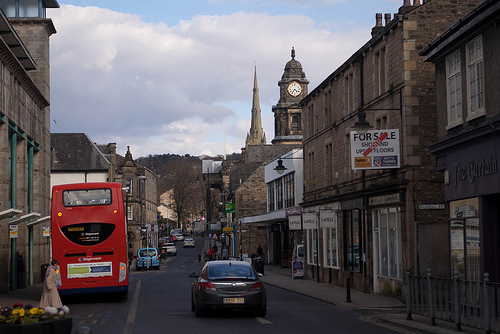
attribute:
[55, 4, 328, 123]
clouds — white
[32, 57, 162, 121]
clouds — white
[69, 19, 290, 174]
sky — blue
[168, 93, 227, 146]
clouds — white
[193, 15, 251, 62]
clouds — white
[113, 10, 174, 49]
clouds — white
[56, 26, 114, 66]
clouds — white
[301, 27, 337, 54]
clouds — white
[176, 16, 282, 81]
clouds — white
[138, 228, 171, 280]
van — blue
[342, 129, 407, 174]
sign — black, white, red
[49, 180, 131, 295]
bus — Red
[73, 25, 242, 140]
clouds — white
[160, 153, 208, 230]
tree — leaveless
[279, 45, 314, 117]
tower — clock, brown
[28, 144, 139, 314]
bus — red, parked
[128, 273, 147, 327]
line — yellow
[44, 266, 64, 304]
coat — long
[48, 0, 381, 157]
sky — blue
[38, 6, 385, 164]
sky — blue